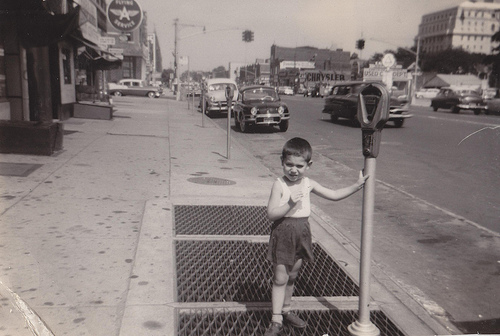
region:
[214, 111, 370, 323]
boy on the sidewalk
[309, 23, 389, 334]
parking meter on pole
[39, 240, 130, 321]
spots on the sidewalk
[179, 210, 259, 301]
grate on the sidewalk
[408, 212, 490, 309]
the road is dirty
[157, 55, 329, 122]
cars on the street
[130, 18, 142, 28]
sign on the side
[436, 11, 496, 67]
building on the right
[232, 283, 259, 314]
shadow of the boy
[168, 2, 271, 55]
traffic light on pole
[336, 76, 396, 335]
parking meter on a silver pole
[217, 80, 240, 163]
parking meter on a silver pole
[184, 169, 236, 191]
large oil stain on the sidewalk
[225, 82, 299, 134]
car parked on the street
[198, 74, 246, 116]
car parked on the street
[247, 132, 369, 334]
child standing next to the street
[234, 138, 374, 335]
child wearing a pair of shorts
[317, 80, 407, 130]
car driving on the street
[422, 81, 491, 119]
car driving on the street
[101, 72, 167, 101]
car driving on the street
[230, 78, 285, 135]
this is a car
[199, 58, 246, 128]
this is a car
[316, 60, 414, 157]
this is a car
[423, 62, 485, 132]
this is a car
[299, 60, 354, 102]
this is a bus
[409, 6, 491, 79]
this is a building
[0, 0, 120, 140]
this is a building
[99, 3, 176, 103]
this is a building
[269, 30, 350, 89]
this is a building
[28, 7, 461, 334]
a boy standing by a parking meter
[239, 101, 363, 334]
the boy is wearing shorts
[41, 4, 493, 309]
this picture was taken years ago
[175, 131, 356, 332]
this child is standing over a sidewalk grate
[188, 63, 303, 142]
these cars are from the 1950s or 1960s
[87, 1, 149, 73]
the name of a business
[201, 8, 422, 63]
traffic lights in the area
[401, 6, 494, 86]
a building along the side of the street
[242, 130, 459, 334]
this child is posing for a photo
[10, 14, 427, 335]
this balck and white picture was taken a long time ago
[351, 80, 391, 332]
a vintage parking meter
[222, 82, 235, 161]
a vintage parking meter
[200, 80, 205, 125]
a vintage parking meter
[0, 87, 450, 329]
a paved city sidewalk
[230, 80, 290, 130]
a vintage black car in street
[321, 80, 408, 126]
a vintage black car in street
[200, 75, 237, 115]
a vintage white car in street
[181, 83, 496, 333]
a paved city street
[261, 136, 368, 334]
a young child standing on sidewalk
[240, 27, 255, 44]
an electric traffic signal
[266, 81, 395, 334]
A young boy next to a parking meter.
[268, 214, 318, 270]
shorts on a child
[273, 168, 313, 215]
shirt on a child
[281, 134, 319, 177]
hair on a boy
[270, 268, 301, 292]
knees of a boy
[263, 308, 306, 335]
feet of a boy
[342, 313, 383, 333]
base of a pole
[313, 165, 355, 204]
arm of a boy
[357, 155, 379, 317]
grey metal meter pole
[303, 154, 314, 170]
ear of a boy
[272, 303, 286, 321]
sock on a boy